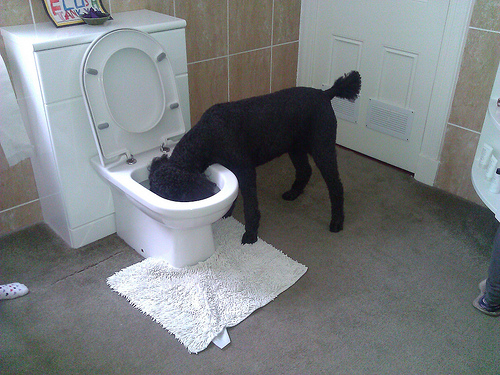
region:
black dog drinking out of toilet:
[77, 15, 358, 253]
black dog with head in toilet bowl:
[151, 73, 388, 251]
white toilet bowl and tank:
[15, 12, 237, 275]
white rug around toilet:
[120, 218, 314, 348]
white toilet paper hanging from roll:
[2, 54, 35, 169]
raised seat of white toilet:
[80, 33, 190, 153]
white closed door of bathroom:
[302, 10, 460, 189]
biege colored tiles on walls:
[5, 3, 488, 183]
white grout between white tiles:
[7, 4, 499, 192]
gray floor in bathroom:
[12, 147, 494, 367]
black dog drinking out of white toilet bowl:
[132, 70, 364, 250]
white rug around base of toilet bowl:
[100, 215, 322, 359]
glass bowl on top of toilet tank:
[72, 5, 119, 27]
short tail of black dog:
[325, 63, 364, 103]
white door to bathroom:
[302, 1, 441, 169]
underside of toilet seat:
[77, 30, 189, 139]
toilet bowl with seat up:
[80, 29, 230, 264]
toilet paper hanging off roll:
[0, 62, 36, 159]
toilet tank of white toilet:
[12, 20, 198, 241]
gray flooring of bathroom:
[11, 135, 499, 364]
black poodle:
[150, 73, 358, 238]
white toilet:
[85, 38, 237, 270]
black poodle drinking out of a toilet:
[85, 34, 361, 267]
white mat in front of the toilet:
[103, 218, 303, 353]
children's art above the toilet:
[50, 0, 114, 27]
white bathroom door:
[299, 3, 469, 186]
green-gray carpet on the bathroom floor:
[2, 140, 494, 373]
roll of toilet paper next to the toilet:
[0, 61, 32, 166]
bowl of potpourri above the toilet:
[87, 9, 112, 26]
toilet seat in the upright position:
[79, 33, 188, 162]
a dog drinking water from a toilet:
[127, 60, 377, 255]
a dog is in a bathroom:
[5, 5, 495, 374]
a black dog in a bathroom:
[136, 64, 379, 255]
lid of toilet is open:
[74, 21, 242, 271]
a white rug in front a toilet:
[78, 155, 315, 364]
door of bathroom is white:
[13, 0, 498, 372]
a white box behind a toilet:
[1, 0, 203, 268]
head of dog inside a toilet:
[104, 127, 239, 280]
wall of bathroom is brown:
[3, 0, 495, 221]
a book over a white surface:
[29, 0, 118, 38]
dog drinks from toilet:
[160, 72, 377, 200]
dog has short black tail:
[330, 80, 376, 105]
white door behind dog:
[285, 8, 443, 180]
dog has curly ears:
[134, 152, 211, 210]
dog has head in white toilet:
[70, 43, 235, 290]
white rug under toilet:
[120, 207, 310, 357]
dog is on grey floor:
[266, 195, 412, 374]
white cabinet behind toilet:
[13, 51, 188, 283]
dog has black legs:
[232, 151, 364, 251]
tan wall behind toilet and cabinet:
[186, 10, 292, 95]